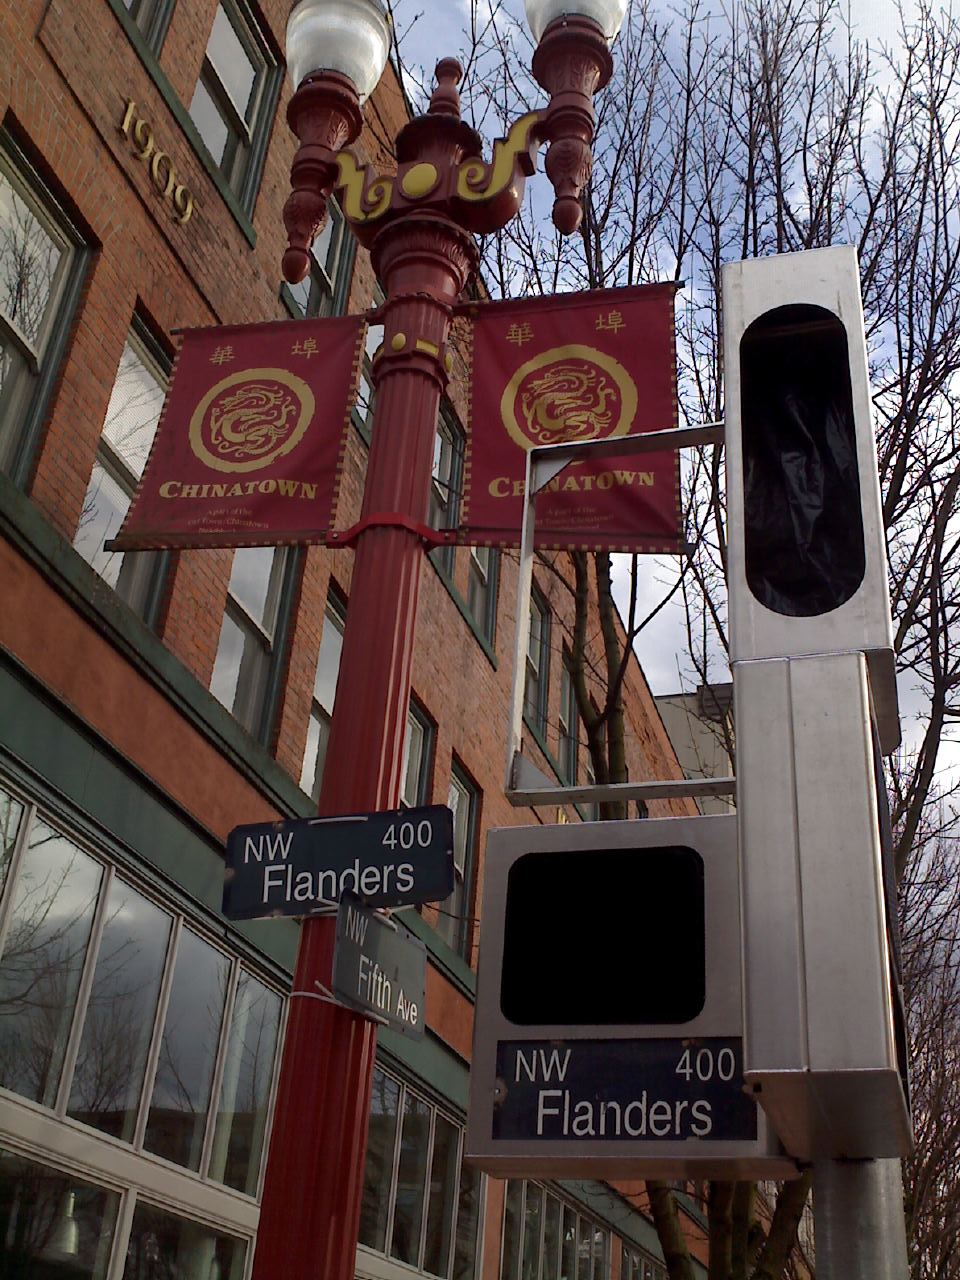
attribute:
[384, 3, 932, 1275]
tree — bare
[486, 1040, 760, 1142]
sign — blue, white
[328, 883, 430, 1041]
sign — white, blue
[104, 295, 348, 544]
banner — red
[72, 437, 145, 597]
window — glass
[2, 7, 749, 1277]
building — orange, green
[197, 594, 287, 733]
window — glass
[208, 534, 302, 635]
window — glass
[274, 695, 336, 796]
window — glass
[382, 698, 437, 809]
window — glass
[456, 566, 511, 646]
window — glass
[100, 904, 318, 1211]
window — glass 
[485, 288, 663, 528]
banner — red 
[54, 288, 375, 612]
banner — red 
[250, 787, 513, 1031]
sign — blue , white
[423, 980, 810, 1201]
sign — white, blue 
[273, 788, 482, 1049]
sign — blue , white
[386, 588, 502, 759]
bricks — black , red 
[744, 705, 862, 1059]
lamp — white 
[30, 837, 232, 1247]
window — large , glass 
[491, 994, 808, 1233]
words — white 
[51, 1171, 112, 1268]
bell — white 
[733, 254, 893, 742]
plastic — black , shiny 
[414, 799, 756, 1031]
plastic — black 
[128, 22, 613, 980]
lamppost — red , gold 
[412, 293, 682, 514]
banner — gold , red 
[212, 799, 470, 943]
street signs — black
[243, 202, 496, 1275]
lamp post — red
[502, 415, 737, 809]
frame — empty, silver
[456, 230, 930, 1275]
pole — silver, rectangular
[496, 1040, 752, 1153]
street sign — black